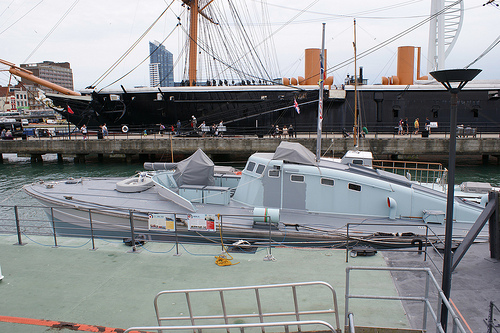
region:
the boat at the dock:
[19, 147, 491, 241]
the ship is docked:
[9, 0, 498, 125]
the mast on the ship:
[170, 1, 220, 83]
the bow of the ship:
[43, 91, 90, 127]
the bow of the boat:
[22, 184, 101, 226]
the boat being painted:
[33, 157, 498, 254]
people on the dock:
[77, 117, 440, 132]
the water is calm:
[5, 163, 49, 209]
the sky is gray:
[11, 5, 166, 50]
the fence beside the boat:
[10, 200, 272, 247]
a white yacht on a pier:
[18, 152, 460, 247]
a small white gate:
[154, 275, 322, 325]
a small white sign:
[135, 199, 179, 234]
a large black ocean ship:
[52, 15, 447, 145]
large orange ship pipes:
[298, 41, 346, 92]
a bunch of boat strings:
[207, 18, 277, 68]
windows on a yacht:
[288, 159, 345, 194]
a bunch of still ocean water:
[5, 161, 42, 198]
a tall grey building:
[30, 56, 81, 97]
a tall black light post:
[422, 58, 483, 260]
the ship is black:
[25, 63, 499, 151]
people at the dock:
[32, 108, 489, 160]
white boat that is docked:
[37, 150, 484, 248]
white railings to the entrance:
[146, 266, 447, 327]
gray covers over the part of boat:
[169, 156, 221, 186]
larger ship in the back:
[59, 0, 495, 125]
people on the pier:
[64, 117, 444, 142]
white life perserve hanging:
[119, 113, 138, 154]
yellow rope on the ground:
[212, 239, 229, 279]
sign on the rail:
[139, 211, 181, 245]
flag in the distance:
[278, 89, 306, 122]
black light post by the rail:
[428, 63, 482, 332]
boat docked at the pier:
[12, 130, 487, 269]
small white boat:
[14, 145, 497, 250]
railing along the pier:
[1, 200, 280, 270]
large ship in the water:
[3, 2, 498, 135]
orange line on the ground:
[1, 311, 126, 331]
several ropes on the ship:
[178, 2, 293, 85]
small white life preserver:
[117, 120, 132, 135]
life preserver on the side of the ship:
[118, 122, 132, 134]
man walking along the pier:
[411, 115, 424, 140]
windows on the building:
[11, 90, 32, 109]